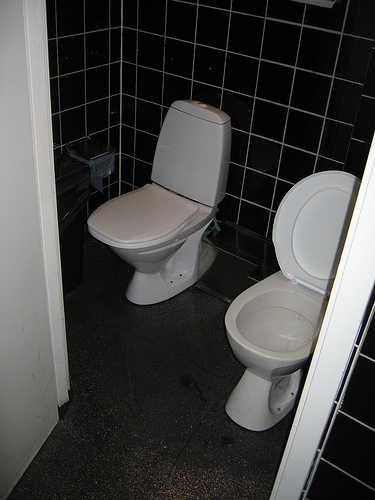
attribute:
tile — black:
[218, 197, 256, 237]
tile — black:
[243, 167, 283, 205]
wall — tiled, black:
[113, 0, 371, 353]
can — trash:
[39, 155, 107, 269]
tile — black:
[244, 135, 283, 179]